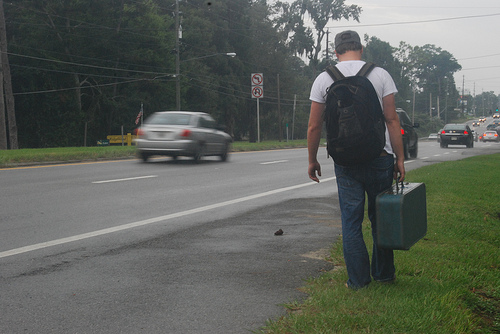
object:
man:
[305, 31, 405, 291]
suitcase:
[373, 180, 430, 251]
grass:
[261, 150, 499, 333]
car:
[133, 108, 233, 163]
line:
[2, 147, 467, 259]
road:
[1, 114, 498, 333]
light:
[181, 127, 192, 138]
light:
[132, 128, 144, 138]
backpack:
[325, 59, 385, 168]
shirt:
[309, 60, 400, 159]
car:
[440, 122, 475, 148]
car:
[392, 108, 420, 159]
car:
[484, 131, 499, 143]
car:
[426, 131, 440, 142]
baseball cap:
[332, 31, 361, 46]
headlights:
[478, 122, 482, 125]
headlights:
[483, 118, 487, 122]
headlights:
[496, 115, 500, 119]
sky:
[261, 2, 500, 93]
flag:
[134, 105, 144, 126]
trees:
[2, 0, 464, 149]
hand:
[391, 164, 408, 183]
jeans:
[332, 152, 398, 286]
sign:
[251, 73, 263, 99]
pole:
[256, 98, 261, 143]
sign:
[251, 85, 264, 99]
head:
[333, 32, 364, 59]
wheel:
[137, 150, 155, 162]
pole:
[140, 102, 145, 125]